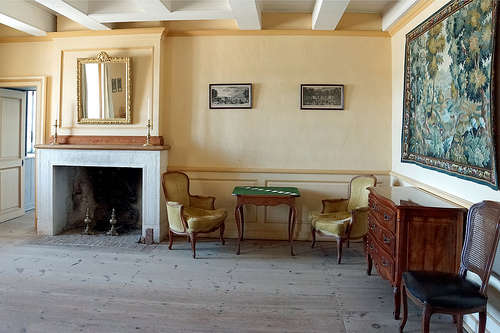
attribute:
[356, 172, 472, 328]
dresser — dark, wood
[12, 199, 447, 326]
rug — hanging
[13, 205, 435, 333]
rug — decorative, woven, hanging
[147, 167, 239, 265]
chair — yellow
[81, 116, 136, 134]
frame — gold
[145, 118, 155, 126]
candle — white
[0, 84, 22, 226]
door — open, beige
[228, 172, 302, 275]
table — small, wood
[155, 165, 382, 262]
chairs — antique, green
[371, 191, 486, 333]
chair — blue, wooden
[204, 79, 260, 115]
painting — large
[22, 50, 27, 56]
rafters — white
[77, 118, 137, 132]
frame — gold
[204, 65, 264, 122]
picture — hanging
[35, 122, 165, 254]
fireplace — white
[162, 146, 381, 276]
chairs — matching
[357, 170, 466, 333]
chest — wooden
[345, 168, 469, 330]
chest — wooden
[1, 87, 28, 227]
door — open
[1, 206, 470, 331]
flooring — gray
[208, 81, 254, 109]
picture frame — dark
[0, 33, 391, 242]
wall — beige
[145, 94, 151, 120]
candle — white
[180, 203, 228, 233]
seat — yellow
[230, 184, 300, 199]
top — green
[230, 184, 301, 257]
table — wooden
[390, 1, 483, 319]
wall — beige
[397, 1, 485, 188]
tapestry — large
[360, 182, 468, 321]
dresser — wooden